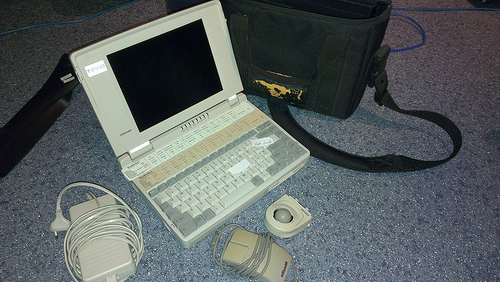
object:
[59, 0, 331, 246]
laptop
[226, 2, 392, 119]
bag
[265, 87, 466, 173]
strap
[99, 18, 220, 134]
screen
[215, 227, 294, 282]
mouse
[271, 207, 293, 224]
trackball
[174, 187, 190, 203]
keys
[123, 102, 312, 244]
keyboard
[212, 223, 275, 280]
cord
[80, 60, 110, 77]
label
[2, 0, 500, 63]
background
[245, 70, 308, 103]
patch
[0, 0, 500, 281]
floor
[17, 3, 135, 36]
cord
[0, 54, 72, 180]
strap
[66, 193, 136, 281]
adapter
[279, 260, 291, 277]
writing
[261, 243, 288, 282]
pad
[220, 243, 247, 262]
buttons